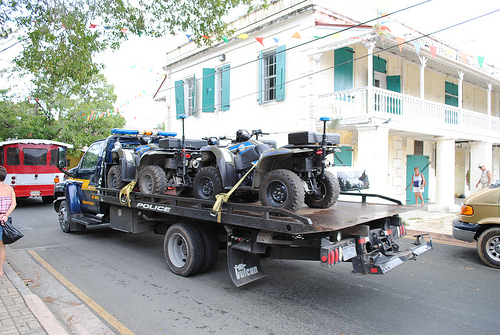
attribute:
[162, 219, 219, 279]
wheel — part 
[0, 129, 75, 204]
bus — red , white 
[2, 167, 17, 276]
woman — holding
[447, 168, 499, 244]
minivan — gold 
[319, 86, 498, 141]
balcony — part 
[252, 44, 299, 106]
window — open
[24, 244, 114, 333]
line — yellow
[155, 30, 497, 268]
building — white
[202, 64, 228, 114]
doors — blue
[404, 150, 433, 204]
door — blue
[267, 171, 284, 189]
wheel — edge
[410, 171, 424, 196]
man — white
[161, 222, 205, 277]
wheel — edge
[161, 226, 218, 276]
wheel — part 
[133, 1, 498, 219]
building — white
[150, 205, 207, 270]
wheel — black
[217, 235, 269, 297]
flap — mud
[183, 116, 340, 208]
bike — dirt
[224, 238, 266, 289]
mud flap — black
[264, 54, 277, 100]
window — blue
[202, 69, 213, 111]
shutter — teal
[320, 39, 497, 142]
balcony — white 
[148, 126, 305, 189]
bikes — dirt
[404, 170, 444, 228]
woman — standing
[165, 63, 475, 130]
story — second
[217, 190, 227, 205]
tie — yellow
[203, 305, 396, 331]
road — edge